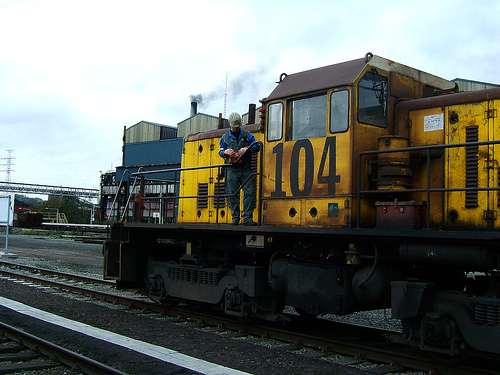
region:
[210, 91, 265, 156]
the head of a man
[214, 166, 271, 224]
the legs of a man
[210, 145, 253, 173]
the hands of a man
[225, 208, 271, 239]
the feet of a man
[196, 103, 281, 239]
a man wearing a hat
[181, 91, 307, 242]
a man standing on a train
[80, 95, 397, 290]
a train on train tracks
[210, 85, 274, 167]
a man wearing a blue shirt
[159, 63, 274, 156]
a building in the background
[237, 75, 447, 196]
numbers on the side of a train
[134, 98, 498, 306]
blue and yellow train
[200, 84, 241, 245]
man is on train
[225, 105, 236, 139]
man has grey helmet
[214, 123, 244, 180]
man has blue shirt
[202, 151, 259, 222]
man has blue pants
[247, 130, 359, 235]
blue numbers on train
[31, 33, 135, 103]
blue and white sky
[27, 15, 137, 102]
white clouds in sky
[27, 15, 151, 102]
thick clouds in sky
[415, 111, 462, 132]
white notice on train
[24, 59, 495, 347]
a train on the tracks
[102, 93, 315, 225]
a man on a yellow train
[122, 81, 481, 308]
the train is yellow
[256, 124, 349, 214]
the train's number is 104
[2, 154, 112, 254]
structures in the background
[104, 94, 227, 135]
a building behind the train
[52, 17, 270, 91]
cloudy skies above the train yard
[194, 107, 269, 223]
this man is the conductor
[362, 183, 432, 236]
a utility box on a train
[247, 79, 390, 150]
window on a train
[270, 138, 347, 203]
black numbers on yellow background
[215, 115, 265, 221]
man standing on side of train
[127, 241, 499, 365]
wheels of the train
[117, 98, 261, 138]
building behind the train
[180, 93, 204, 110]
smoke stack on the building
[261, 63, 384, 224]
conductor's booth on the train car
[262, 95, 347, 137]
windows on side of train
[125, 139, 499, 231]
black rails on the train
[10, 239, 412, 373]
tracks train is on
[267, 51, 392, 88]
roof of conductor's booth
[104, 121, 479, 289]
yellow and blue train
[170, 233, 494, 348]
black wheels on train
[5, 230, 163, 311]
train on black tracks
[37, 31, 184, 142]
white and cloudy sky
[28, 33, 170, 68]
heavy clouds in sky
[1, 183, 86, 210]
black bridge in distance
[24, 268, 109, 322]
grey gravel on tracks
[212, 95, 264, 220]
man is on train